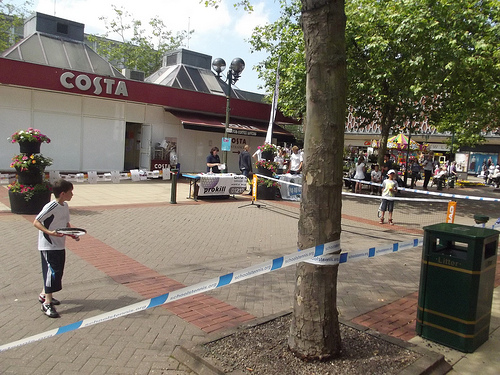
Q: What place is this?
A: It is a restaurant.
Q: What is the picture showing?
A: It is showing a restaurant.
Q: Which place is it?
A: It is a restaurant.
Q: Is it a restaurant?
A: Yes, it is a restaurant.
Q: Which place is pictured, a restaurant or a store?
A: It is a restaurant.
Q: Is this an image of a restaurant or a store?
A: It is showing a restaurant.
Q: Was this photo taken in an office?
A: No, the picture was taken in a restaurant.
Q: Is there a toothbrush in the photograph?
A: No, there are no toothbrushes.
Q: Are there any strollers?
A: No, there are no strollers.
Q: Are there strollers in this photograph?
A: No, there are no strollers.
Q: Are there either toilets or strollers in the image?
A: No, there are no strollers or toilets.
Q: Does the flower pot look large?
A: Yes, the flower pot is large.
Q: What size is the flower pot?
A: The flower pot is large.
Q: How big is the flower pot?
A: The flower pot is large.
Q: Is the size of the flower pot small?
A: No, the flower pot is large.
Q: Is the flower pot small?
A: No, the flower pot is large.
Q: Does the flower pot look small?
A: No, the flower pot is large.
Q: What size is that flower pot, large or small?
A: The flower pot is large.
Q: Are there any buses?
A: No, there are no buses.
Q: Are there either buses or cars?
A: No, there are no buses or cars.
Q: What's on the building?
A: The sign is on the building.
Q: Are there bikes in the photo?
A: No, there are no bikes.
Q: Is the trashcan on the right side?
A: Yes, the trashcan is on the right of the image.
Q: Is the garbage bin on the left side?
A: No, the garbage bin is on the right of the image.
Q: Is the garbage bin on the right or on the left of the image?
A: The garbage bin is on the right of the image.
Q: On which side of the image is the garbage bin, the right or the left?
A: The garbage bin is on the right of the image.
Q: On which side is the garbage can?
A: The garbage can is on the right of the image.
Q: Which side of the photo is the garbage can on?
A: The garbage can is on the right of the image.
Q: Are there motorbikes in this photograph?
A: No, there are no motorbikes.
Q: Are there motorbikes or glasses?
A: No, there are no motorbikes or glasses.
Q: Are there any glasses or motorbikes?
A: No, there are no motorbikes or glasses.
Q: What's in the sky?
A: The clouds are in the sky.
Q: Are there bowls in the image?
A: No, there are no bowls.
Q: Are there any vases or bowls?
A: No, there are no bowls or vases.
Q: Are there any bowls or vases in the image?
A: No, there are no bowls or vases.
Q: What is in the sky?
A: The clouds are in the sky.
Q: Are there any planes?
A: No, there are no planes.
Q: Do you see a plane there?
A: No, there are no airplanes.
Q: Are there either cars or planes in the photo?
A: No, there are no planes or cars.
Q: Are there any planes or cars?
A: No, there are no planes or cars.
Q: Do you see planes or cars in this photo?
A: No, there are no planes or cars.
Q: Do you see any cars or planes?
A: No, there are no planes or cars.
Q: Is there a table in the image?
A: Yes, there is a table.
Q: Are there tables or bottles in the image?
A: Yes, there is a table.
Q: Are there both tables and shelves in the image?
A: No, there is a table but no shelves.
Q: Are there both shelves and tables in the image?
A: No, there is a table but no shelves.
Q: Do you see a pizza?
A: No, there are no pizzas.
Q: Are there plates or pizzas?
A: No, there are no pizzas or plates.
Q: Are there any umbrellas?
A: Yes, there is an umbrella.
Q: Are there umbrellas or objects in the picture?
A: Yes, there is an umbrella.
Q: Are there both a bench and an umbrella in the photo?
A: No, there is an umbrella but no benches.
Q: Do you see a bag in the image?
A: No, there are no bags.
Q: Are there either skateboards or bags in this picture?
A: No, there are no bags or skateboards.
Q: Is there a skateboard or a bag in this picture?
A: No, there are no bags or skateboards.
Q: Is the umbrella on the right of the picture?
A: Yes, the umbrella is on the right of the image.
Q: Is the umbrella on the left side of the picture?
A: No, the umbrella is on the right of the image.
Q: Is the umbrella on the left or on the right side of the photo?
A: The umbrella is on the right of the image.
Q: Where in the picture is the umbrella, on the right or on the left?
A: The umbrella is on the right of the image.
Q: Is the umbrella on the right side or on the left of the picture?
A: The umbrella is on the right of the image.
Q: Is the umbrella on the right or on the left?
A: The umbrella is on the right of the image.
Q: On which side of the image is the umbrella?
A: The umbrella is on the right of the image.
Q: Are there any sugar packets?
A: No, there are no sugar packets.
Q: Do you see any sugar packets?
A: No, there are no sugar packets.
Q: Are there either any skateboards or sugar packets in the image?
A: No, there are no sugar packets or skateboards.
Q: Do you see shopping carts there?
A: No, there are no shopping carts.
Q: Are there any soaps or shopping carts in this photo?
A: No, there are no shopping carts or soaps.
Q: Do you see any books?
A: No, there are no books.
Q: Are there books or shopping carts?
A: No, there are no books or shopping carts.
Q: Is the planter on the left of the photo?
A: Yes, the planter is on the left of the image.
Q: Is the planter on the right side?
A: No, the planter is on the left of the image.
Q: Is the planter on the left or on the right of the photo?
A: The planter is on the left of the image.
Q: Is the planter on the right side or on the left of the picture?
A: The planter is on the left of the image.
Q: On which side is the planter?
A: The planter is on the left of the image.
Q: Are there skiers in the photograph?
A: No, there are no skiers.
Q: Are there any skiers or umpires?
A: No, there are no skiers or umpires.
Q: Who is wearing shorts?
A: The boy is wearing shorts.